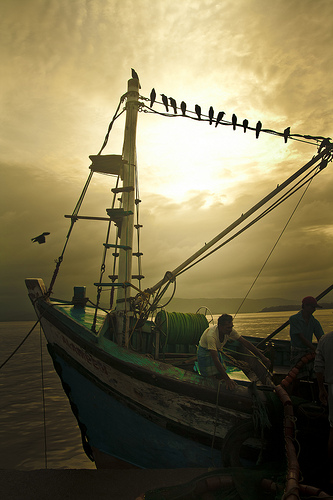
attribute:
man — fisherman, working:
[288, 291, 325, 358]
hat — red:
[301, 293, 322, 309]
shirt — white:
[199, 326, 243, 351]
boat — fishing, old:
[27, 63, 332, 467]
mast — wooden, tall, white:
[111, 77, 142, 342]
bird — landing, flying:
[29, 229, 56, 245]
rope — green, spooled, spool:
[170, 308, 207, 342]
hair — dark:
[216, 311, 235, 327]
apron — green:
[195, 346, 227, 379]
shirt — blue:
[288, 314, 323, 339]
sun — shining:
[133, 71, 291, 206]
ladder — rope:
[95, 168, 133, 322]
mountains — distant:
[2, 295, 332, 319]